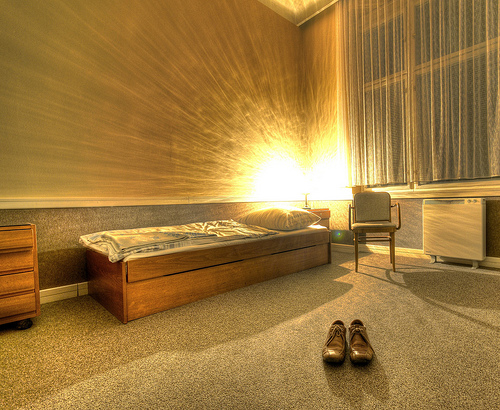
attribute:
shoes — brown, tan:
[321, 318, 375, 366]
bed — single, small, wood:
[80, 204, 332, 324]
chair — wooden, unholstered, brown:
[346, 189, 403, 274]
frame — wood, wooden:
[83, 228, 334, 324]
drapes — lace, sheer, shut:
[344, 0, 499, 188]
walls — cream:
[0, 0, 350, 200]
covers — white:
[79, 218, 327, 265]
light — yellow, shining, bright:
[264, 148, 349, 205]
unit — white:
[421, 195, 490, 271]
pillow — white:
[237, 204, 322, 232]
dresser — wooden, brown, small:
[0, 220, 42, 334]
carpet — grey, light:
[1, 246, 499, 406]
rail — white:
[0, 194, 309, 208]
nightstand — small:
[305, 207, 333, 228]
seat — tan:
[350, 190, 398, 233]